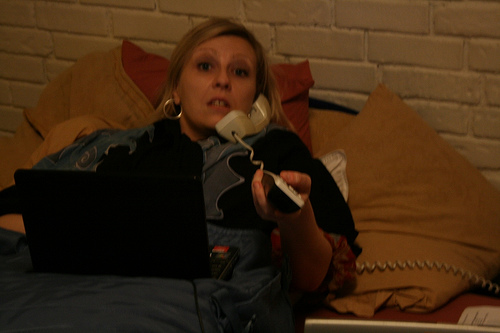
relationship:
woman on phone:
[138, 31, 346, 262] [217, 89, 283, 151]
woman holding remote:
[138, 31, 346, 262] [253, 163, 309, 217]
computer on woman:
[20, 160, 237, 280] [138, 31, 346, 262]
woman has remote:
[138, 31, 346, 262] [253, 163, 309, 217]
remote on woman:
[253, 163, 309, 217] [138, 31, 346, 262]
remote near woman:
[253, 163, 309, 217] [138, 31, 346, 262]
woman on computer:
[138, 31, 346, 262] [20, 160, 237, 280]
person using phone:
[1, 27, 357, 331] [217, 89, 283, 151]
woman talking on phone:
[0, 15, 363, 333] [219, 96, 268, 138]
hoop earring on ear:
[163, 95, 183, 119] [171, 79, 182, 106]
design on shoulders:
[3, 128, 359, 257] [216, 129, 356, 239]